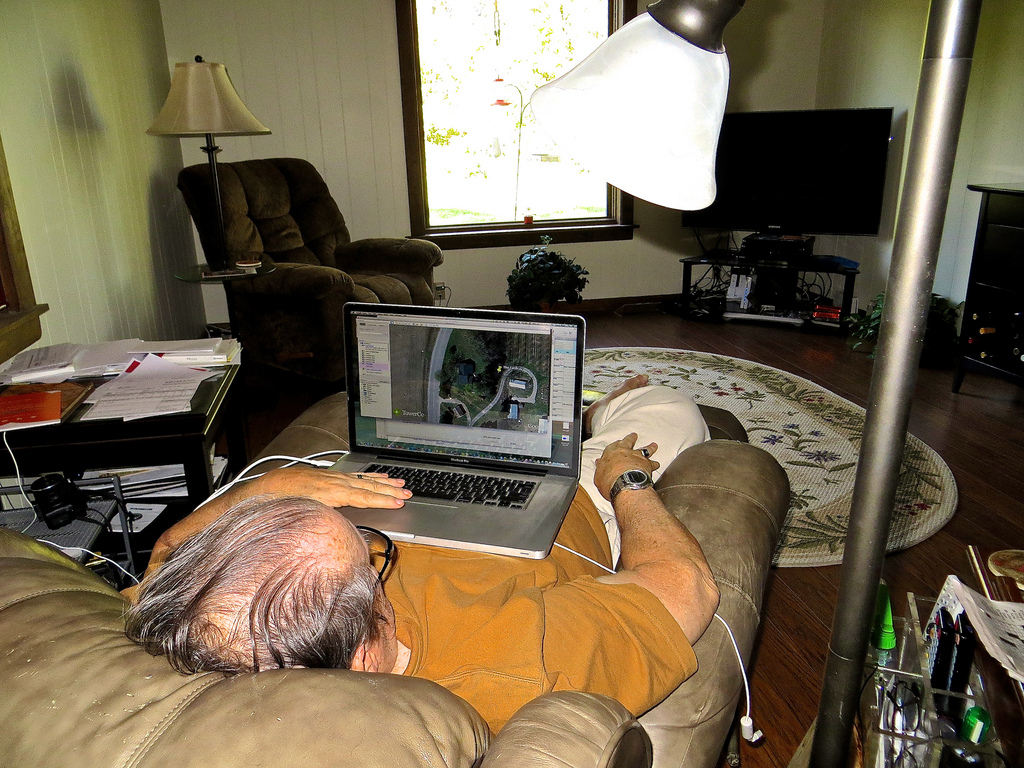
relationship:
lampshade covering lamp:
[148, 61, 276, 145] [140, 52, 273, 274]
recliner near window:
[175, 146, 447, 390] [399, 0, 627, 251]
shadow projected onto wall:
[44, 52, 147, 331] [0, 0, 181, 345]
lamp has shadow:
[147, 56, 275, 272] [44, 52, 147, 331]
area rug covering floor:
[559, 339, 958, 581] [575, 308, 1022, 762]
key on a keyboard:
[483, 498, 503, 511] [361, 450, 536, 507]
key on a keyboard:
[431, 477, 444, 488] [355, 460, 529, 505]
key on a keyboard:
[459, 485, 476, 496] [363, 455, 535, 523]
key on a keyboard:
[404, 468, 428, 484] [360, 462, 535, 517]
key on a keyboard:
[486, 471, 502, 487] [360, 449, 538, 516]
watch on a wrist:
[608, 471, 663, 504] [606, 461, 661, 501]